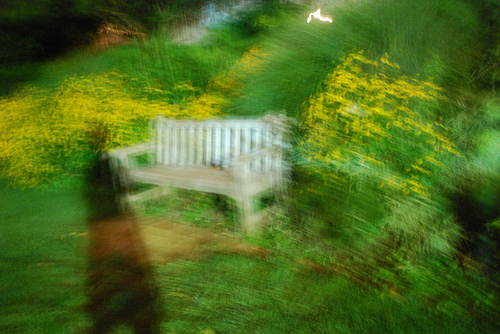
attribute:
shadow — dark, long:
[71, 119, 182, 332]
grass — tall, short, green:
[0, 0, 499, 334]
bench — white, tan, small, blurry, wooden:
[93, 101, 308, 240]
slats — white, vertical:
[161, 133, 244, 165]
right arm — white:
[227, 141, 279, 186]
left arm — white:
[105, 125, 155, 173]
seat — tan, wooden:
[141, 158, 247, 195]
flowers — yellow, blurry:
[7, 52, 441, 191]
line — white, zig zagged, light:
[296, 1, 353, 30]